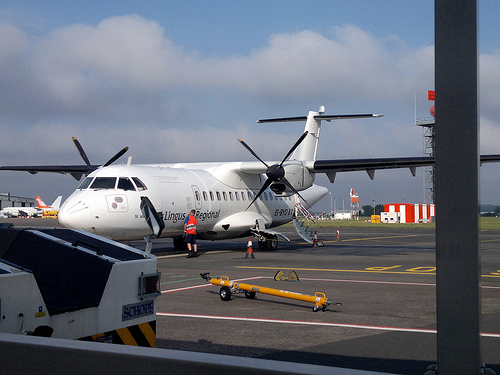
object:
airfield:
[0, 190, 499, 375]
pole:
[200, 272, 343, 313]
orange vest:
[186, 215, 197, 235]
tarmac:
[332, 246, 452, 335]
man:
[182, 209, 198, 258]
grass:
[286, 216, 497, 231]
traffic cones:
[312, 225, 341, 247]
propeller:
[237, 131, 313, 214]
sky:
[0, 0, 499, 204]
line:
[218, 312, 304, 331]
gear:
[22, 91, 494, 287]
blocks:
[252, 249, 330, 301]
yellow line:
[231, 263, 500, 279]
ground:
[117, 214, 499, 374]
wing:
[309, 154, 500, 183]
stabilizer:
[256, 105, 384, 124]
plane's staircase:
[293, 200, 324, 246]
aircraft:
[0, 103, 386, 251]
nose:
[56, 198, 90, 232]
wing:
[0, 163, 98, 182]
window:
[77, 176, 145, 190]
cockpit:
[74, 170, 149, 205]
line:
[246, 259, 373, 278]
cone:
[244, 236, 255, 259]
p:
[365, 265, 402, 271]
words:
[134, 209, 220, 223]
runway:
[3, 230, 500, 372]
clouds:
[1, 0, 500, 210]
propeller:
[0, 135, 126, 181]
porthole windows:
[195, 190, 292, 201]